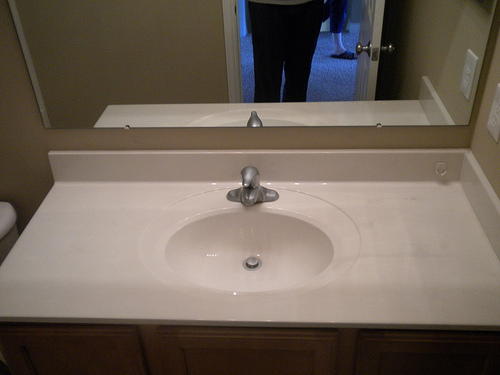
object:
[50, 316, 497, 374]
doors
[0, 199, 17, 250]
toilet tank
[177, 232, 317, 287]
metal sink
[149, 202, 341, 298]
plane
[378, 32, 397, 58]
knob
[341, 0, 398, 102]
door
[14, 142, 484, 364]
bathroom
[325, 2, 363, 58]
person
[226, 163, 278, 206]
faucet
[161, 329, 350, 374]
door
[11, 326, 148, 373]
door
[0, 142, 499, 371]
cabinet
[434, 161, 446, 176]
device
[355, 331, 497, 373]
door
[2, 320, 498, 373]
cabinet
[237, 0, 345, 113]
person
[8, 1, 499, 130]
mirror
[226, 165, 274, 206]
metal part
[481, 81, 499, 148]
wall plug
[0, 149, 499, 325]
sink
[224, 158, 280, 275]
metal part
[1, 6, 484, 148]
wall